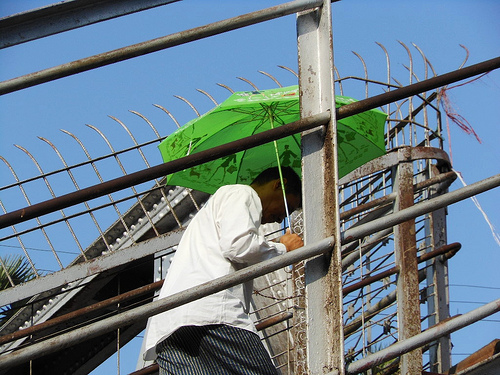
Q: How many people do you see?
A: Only one.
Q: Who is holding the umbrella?
A: The man.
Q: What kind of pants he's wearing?
A: Striped pants.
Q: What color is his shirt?
A: All white.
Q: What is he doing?
A: He's walking.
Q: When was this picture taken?
A: IN the day.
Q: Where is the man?
A: On the steps.